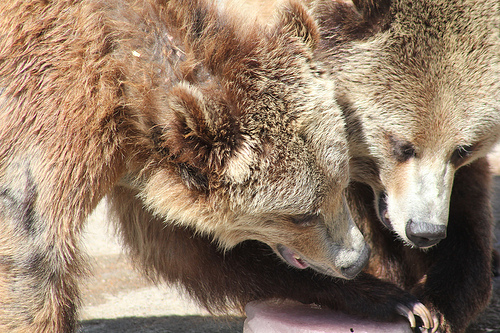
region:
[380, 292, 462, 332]
long bear claws that look almost like a human comestible, but not quite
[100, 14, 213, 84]
leaves+sticks+mud+goop on the bare neck beside a bear head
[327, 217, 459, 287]
two very similar black noses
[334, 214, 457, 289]
wet & leathery sniffy noses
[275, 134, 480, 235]
three & one half visible dark brown eyes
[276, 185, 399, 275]
pink lips inside black lips, yellowish off-white teeth embedded w/in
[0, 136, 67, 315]
a dark brown heavily furred upper bare bear arm & elbow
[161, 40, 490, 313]
Two brown bears together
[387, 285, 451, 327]
Claw of the bear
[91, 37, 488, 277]
Two brown bears looking down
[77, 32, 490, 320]
Two brown bears trying to open something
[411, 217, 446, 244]
Nose of a bear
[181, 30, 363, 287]
Head of a bear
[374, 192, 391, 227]
Mouth of a bear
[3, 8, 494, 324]
two bears clawing an object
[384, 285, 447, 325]
a bear's front claws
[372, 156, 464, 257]
nose and mouth of the right bear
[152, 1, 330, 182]
ears of a bear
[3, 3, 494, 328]
two brown bears are playing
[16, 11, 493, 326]
two brown bears are clawing something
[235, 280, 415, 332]
a white object the bear is clawing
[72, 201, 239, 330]
dirt on the ground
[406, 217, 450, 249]
the bear has a black nose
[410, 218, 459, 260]
Bear ha black nose.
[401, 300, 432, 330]
Bear has long claws.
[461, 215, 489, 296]
Bear has brown front leg.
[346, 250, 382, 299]
Bear has black nose.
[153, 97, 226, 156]
Bear has brown ear.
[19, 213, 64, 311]
Bear has brown front leg.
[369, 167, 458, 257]
Snout of a wolf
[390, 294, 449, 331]
Drawn long sharp claws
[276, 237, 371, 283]
Open mouth with white tooth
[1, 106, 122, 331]
Hairy leg of a wolf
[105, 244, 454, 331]
Long leg with claws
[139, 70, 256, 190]
Hairy ear of a wolf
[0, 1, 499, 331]
Wolves with thick hair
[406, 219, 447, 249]
More visible black bear nose.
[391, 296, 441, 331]
Four bear claws on a bear.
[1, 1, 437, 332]
A larger bear with claws out.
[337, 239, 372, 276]
Black nose on the largest brown bear.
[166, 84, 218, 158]
A bears right brown ear.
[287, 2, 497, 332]
A smaller brown bear.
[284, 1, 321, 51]
A brown bears left ear.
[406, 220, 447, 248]
A more black nose on a bear.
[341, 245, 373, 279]
A less visible black nose.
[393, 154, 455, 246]
Whiter bear snout with blacker nose.